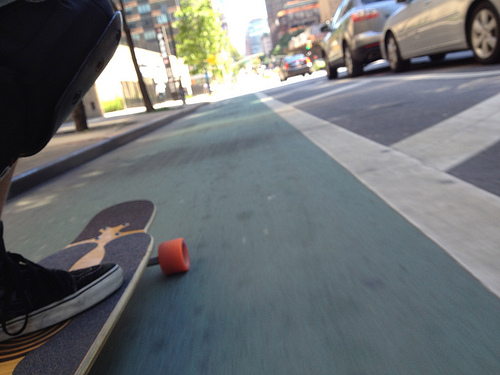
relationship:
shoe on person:
[0, 217, 124, 344] [0, 0, 123, 343]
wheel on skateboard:
[158, 237, 191, 276] [2, 197, 192, 373]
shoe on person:
[0, 248, 124, 341] [2, 3, 133, 350]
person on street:
[2, 3, 133, 350] [1, 72, 498, 372]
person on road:
[0, 0, 123, 343] [3, 77, 499, 373]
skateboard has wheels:
[0, 199, 190, 375] [158, 237, 198, 294]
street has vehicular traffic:
[1, 72, 498, 372] [380, 0, 498, 73]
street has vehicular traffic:
[1, 72, 498, 372] [306, 0, 388, 74]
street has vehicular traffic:
[1, 72, 498, 372] [274, 47, 311, 79]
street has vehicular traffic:
[1, 72, 498, 372] [0, 0, 188, 374]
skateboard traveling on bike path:
[30, 164, 229, 352] [2, 94, 498, 374]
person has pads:
[0, 0, 123, 343] [0, 0, 125, 162]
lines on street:
[251, 93, 500, 299] [1, 72, 498, 372]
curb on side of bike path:
[8, 97, 209, 202] [2, 94, 498, 374]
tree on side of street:
[170, 1, 224, 96] [191, 45, 296, 133]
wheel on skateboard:
[147, 235, 191, 275] [2, 197, 192, 373]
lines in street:
[304, 95, 463, 251] [200, 100, 496, 258]